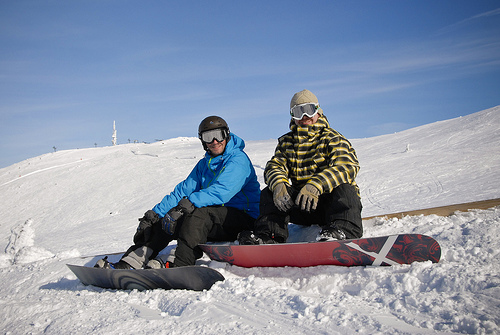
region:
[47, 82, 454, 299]
two people sitting with snowboards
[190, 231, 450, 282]
red white black snow board in snow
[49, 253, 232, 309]
grey and blue snowboard in snow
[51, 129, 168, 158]
several people on top of snow hill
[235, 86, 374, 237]
guy with snowsuit on sitting down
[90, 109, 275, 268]
guy with snowsuit on sitting down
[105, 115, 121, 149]
snow covered tree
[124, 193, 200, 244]
two black snow gloves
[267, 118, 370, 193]
yellow and black jacket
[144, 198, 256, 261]
black men's snow pants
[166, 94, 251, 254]
snowboarder sitting on slope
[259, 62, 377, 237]
snowboarder sitting on slope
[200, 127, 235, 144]
silver goggles on snowboarder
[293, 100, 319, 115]
silver goggles on snowboarder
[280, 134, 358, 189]
yellow plaid snow jacket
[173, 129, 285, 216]
blue snow jacket on boarder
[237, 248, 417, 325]
tracks and footprints in snow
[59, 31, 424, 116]
blue sky above slope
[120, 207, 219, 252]
black pants on snowboarder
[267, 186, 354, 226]
black pants on snowboarder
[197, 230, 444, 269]
Man on a board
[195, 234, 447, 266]
Man is on a board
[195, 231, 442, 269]
Man on a red and black board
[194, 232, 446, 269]
Man is on a red and black board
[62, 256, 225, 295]
Man on a snowboard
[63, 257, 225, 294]
Man is on a snowboard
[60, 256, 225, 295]
Man on a black and gray board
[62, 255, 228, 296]
Man is on a black and gray board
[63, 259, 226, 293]
Man on a black and gray snowboard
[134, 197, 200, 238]
Man is wearing gloves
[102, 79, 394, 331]
two men sitting in the snow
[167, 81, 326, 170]
two men wearing goggles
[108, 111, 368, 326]
two men wearing snowboards on their feet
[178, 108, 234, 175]
a man wearing a helmet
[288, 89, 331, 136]
a man wearing a hat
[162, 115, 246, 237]
a man wearing a blue jacket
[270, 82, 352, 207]
a man wearing a yellow and black coat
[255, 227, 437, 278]
a red and black snowboard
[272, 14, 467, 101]
white clouds in a blue sky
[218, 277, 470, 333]
tracks in the snow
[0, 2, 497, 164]
blue in daytime sky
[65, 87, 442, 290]
two people sitting on snow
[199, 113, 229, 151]
black helmet on man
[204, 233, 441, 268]
bottom of snowboard in snow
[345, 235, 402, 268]
white x on snowboard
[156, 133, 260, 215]
blue jacket with hood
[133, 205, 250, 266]
black pants on man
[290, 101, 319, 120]
mirrored goggles on man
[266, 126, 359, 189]
black and yellow jacket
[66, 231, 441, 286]
two sideways snowboards in snow